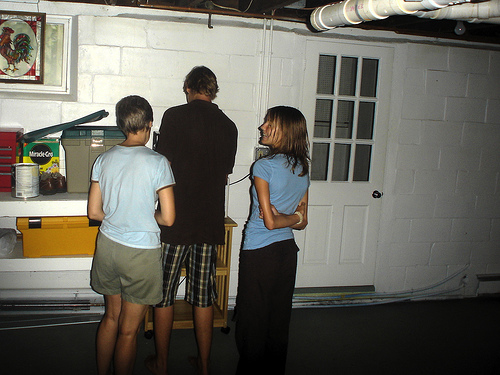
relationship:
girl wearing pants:
[226, 106, 313, 372] [235, 235, 300, 371]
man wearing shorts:
[145, 62, 241, 374] [161, 238, 221, 313]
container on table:
[60, 123, 127, 194] [1, 193, 88, 218]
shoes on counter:
[40, 173, 67, 194] [1, 192, 89, 216]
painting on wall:
[0, 8, 46, 86] [78, 13, 267, 110]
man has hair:
[163, 62, 224, 372] [175, 64, 220, 96]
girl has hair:
[226, 104, 314, 374] [280, 102, 304, 162]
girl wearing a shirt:
[226, 104, 314, 374] [247, 148, 310, 243]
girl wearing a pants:
[226, 104, 314, 374] [234, 236, 294, 371]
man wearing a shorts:
[145, 62, 241, 374] [157, 217, 221, 313]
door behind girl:
[299, 38, 393, 318] [226, 104, 314, 374]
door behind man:
[299, 38, 393, 318] [145, 62, 241, 374]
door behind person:
[299, 38, 393, 318] [86, 90, 177, 370]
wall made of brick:
[381, 41, 498, 290] [441, 90, 491, 126]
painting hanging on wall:
[0, 11, 49, 92] [1, 2, 266, 113]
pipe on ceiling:
[311, 1, 496, 22] [149, 1, 497, 33]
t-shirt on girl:
[243, 150, 309, 250] [226, 106, 313, 372]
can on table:
[14, 158, 42, 199] [3, 189, 113, 305]